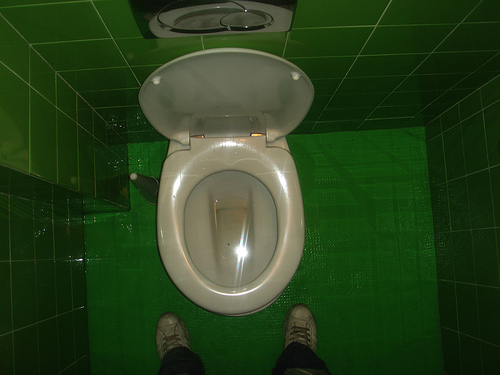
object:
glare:
[230, 241, 251, 262]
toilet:
[140, 47, 315, 317]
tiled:
[83, 125, 446, 374]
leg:
[156, 356, 207, 374]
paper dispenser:
[126, 2, 298, 40]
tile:
[466, 168, 497, 228]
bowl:
[180, 166, 280, 287]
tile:
[359, 26, 459, 57]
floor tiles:
[350, 250, 375, 285]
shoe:
[155, 310, 190, 364]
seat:
[156, 133, 306, 314]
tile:
[11, 258, 38, 332]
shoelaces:
[288, 324, 313, 347]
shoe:
[284, 302, 318, 352]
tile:
[326, 74, 409, 98]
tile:
[129, 143, 149, 165]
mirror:
[145, 0, 292, 38]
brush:
[126, 169, 161, 204]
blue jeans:
[157, 341, 329, 373]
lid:
[136, 48, 315, 145]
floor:
[83, 126, 441, 374]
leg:
[274, 347, 334, 374]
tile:
[27, 50, 59, 108]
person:
[156, 302, 332, 374]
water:
[211, 192, 253, 272]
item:
[417, 230, 436, 286]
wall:
[0, 0, 500, 142]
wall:
[426, 78, 500, 374]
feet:
[156, 309, 193, 359]